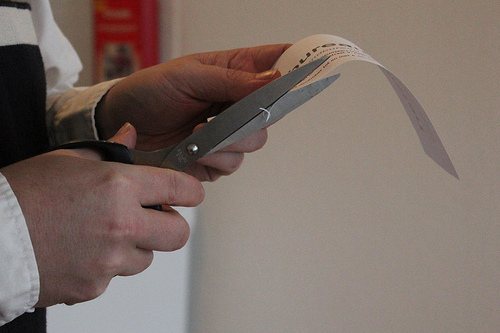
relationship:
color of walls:
[401, 25, 462, 69] [50, 3, 500, 332]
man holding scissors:
[0, 1, 307, 325] [47, 51, 339, 185]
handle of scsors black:
[47, 135, 156, 173] [105, 146, 124, 158]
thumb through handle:
[106, 118, 139, 147] [47, 135, 156, 173]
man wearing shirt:
[0, 1, 307, 325] [2, 2, 119, 240]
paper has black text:
[247, 33, 469, 183] [295, 41, 340, 64]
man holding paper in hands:
[0, 1, 307, 325] [102, 42, 294, 183]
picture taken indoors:
[0, 0, 499, 331] [49, 5, 497, 331]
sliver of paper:
[254, 95, 277, 122] [247, 33, 469, 183]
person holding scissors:
[0, 1, 307, 325] [47, 51, 339, 185]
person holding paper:
[0, 1, 307, 325] [247, 33, 469, 183]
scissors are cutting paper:
[47, 51, 339, 185] [247, 33, 469, 183]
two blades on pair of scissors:
[184, 57, 343, 154] [47, 51, 339, 185]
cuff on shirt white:
[0, 174, 41, 324] [5, 215, 24, 255]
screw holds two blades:
[185, 140, 202, 157] [184, 57, 343, 154]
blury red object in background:
[89, 2, 165, 88] [16, 3, 492, 329]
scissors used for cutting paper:
[47, 51, 339, 185] [247, 33, 469, 183]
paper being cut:
[247, 33, 469, 183] [254, 59, 353, 144]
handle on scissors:
[47, 135, 156, 173] [47, 51, 339, 185]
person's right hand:
[0, 1, 307, 325] [13, 126, 209, 298]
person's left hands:
[0, 1, 307, 325] [102, 42, 294, 183]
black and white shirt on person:
[11, 18, 44, 99] [0, 1, 307, 325]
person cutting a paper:
[0, 1, 307, 325] [247, 33, 469, 183]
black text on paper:
[298, 40, 342, 61] [247, 33, 469, 183]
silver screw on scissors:
[185, 140, 202, 157] [47, 51, 339, 185]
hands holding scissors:
[40, 40, 315, 286] [47, 51, 339, 185]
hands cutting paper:
[40, 40, 315, 286] [247, 33, 469, 183]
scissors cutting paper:
[47, 51, 339, 185] [247, 33, 469, 183]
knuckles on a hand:
[95, 171, 133, 281] [13, 126, 209, 298]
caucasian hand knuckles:
[44, 165, 95, 202] [95, 171, 133, 281]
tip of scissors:
[310, 52, 346, 92] [47, 51, 339, 185]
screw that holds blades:
[185, 140, 202, 157] [184, 57, 343, 154]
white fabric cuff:
[5, 215, 24, 255] [0, 174, 41, 324]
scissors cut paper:
[47, 51, 339, 185] [247, 33, 469, 183]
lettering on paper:
[298, 40, 342, 61] [247, 33, 469, 183]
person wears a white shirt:
[0, 1, 307, 325] [2, 2, 119, 240]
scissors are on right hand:
[47, 51, 339, 185] [13, 126, 209, 298]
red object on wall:
[89, 2, 165, 88] [46, 0, 189, 88]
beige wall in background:
[396, 9, 479, 68] [16, 3, 492, 329]